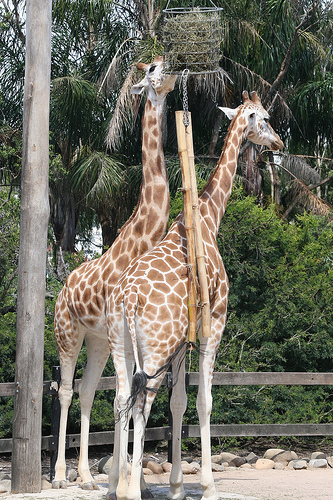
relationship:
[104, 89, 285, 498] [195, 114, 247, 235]
giraffe has neck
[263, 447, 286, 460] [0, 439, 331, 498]
rock on ground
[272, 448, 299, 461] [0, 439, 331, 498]
rock on ground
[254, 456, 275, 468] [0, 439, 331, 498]
rock on ground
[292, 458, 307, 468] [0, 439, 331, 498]
rock on ground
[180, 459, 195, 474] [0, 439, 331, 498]
rock on ground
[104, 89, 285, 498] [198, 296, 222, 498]
giraffe has leg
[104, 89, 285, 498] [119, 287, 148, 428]
giraffe has tail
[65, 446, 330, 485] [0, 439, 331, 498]
rocks on ground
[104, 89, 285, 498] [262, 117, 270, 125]
giraffe has eye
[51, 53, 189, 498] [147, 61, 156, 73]
giraffe has eye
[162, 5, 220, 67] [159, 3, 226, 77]
hay in basket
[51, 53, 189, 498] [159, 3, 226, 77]
giraffe eating from basket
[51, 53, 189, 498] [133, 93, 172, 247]
giraffe has neck